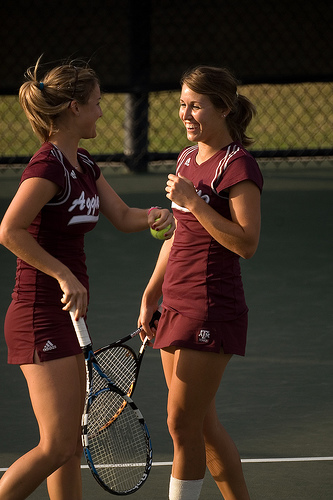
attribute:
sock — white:
[169, 476, 205, 499]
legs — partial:
[159, 349, 258, 499]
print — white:
[51, 147, 107, 223]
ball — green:
[148, 216, 172, 241]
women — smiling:
[1, 65, 264, 500]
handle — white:
[70, 306, 92, 348]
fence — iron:
[1, 0, 332, 171]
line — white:
[1, 456, 332, 474]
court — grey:
[1, 166, 332, 500]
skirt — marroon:
[151, 307, 252, 353]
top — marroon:
[162, 144, 264, 284]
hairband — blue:
[36, 79, 48, 93]